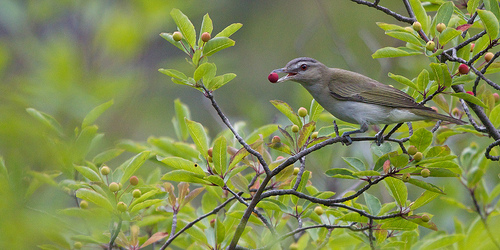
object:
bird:
[269, 57, 468, 147]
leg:
[377, 124, 388, 134]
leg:
[345, 127, 370, 136]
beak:
[268, 67, 292, 83]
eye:
[299, 63, 309, 71]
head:
[269, 56, 329, 88]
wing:
[326, 78, 435, 112]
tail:
[403, 108, 469, 126]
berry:
[267, 71, 279, 83]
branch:
[229, 135, 400, 249]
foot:
[337, 132, 353, 146]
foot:
[375, 134, 386, 146]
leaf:
[369, 45, 424, 59]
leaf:
[386, 70, 420, 93]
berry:
[170, 30, 184, 42]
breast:
[318, 91, 349, 121]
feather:
[328, 80, 362, 98]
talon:
[343, 140, 353, 146]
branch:
[470, 188, 500, 248]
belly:
[329, 100, 391, 126]